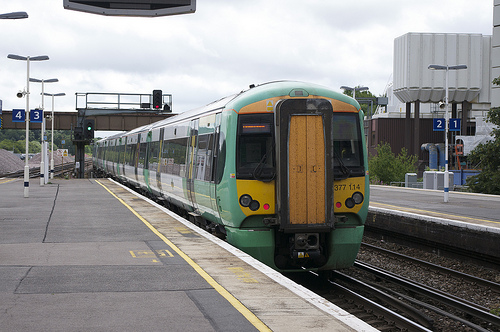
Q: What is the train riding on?
A: A track.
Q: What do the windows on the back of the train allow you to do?
A: See out of them.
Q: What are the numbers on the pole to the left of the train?
A: 4 and 3.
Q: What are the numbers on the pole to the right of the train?
A: 2 and 1.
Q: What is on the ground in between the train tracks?
A: Rocks and gravel.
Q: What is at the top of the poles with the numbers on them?
A: Lights.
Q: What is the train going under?
A: A bridge.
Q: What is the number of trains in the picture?
A: One.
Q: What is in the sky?
A: Clouds.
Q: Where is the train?
A: On train tracks.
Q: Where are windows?
A: On the train.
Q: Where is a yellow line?
A: On the ground.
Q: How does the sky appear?
A: Cloudy.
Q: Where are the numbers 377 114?
A: On front of the train.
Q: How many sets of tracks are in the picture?
A: Two.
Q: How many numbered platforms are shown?
A: Four.